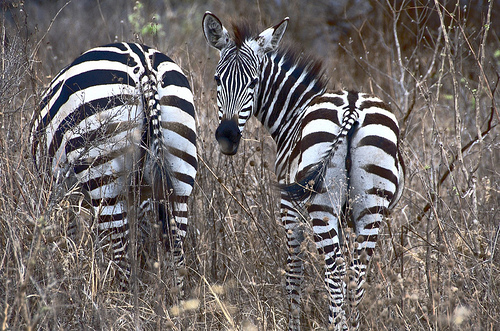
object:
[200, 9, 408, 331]
zebra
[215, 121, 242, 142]
nose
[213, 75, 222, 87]
eyes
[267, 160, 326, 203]
hair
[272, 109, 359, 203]
tail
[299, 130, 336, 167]
stripes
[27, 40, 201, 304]
zebra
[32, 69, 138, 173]
stripes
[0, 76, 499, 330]
grass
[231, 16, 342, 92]
mane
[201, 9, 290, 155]
head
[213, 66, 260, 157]
face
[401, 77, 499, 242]
twig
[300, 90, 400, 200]
rear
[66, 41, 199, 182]
rear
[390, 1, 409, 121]
branches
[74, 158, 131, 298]
legs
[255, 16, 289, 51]
ear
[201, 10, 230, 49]
ear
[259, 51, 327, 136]
neck